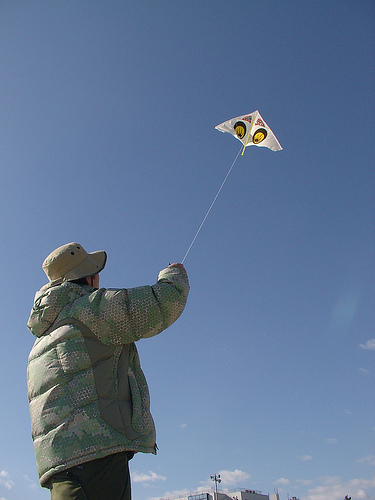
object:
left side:
[213, 109, 257, 148]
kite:
[212, 107, 283, 158]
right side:
[247, 109, 283, 151]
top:
[209, 470, 223, 483]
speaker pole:
[211, 471, 223, 499]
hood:
[29, 281, 83, 336]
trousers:
[46, 449, 138, 498]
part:
[58, 318, 143, 440]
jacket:
[25, 264, 192, 491]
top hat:
[40, 241, 109, 284]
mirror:
[201, 491, 207, 499]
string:
[176, 146, 243, 267]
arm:
[101, 263, 192, 346]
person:
[23, 239, 194, 500]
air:
[2, 1, 374, 500]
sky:
[0, 0, 374, 499]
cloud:
[128, 469, 168, 485]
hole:
[68, 248, 77, 258]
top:
[230, 490, 271, 500]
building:
[226, 487, 268, 499]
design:
[251, 126, 269, 145]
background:
[0, 1, 373, 499]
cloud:
[201, 466, 256, 486]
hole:
[74, 244, 83, 254]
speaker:
[214, 473, 223, 481]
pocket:
[126, 368, 142, 431]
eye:
[232, 119, 248, 141]